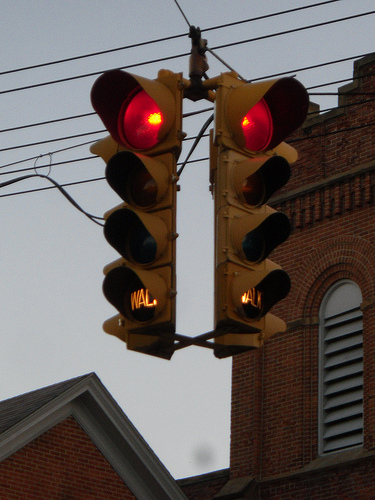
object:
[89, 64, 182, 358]
traffic lights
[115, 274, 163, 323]
yellow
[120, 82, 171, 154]
light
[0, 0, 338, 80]
wires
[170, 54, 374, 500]
building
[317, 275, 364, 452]
arched windows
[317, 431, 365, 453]
downwards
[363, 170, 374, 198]
bricks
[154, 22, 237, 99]
support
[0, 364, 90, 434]
roof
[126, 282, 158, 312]
yellow words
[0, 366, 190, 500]
building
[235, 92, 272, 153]
red